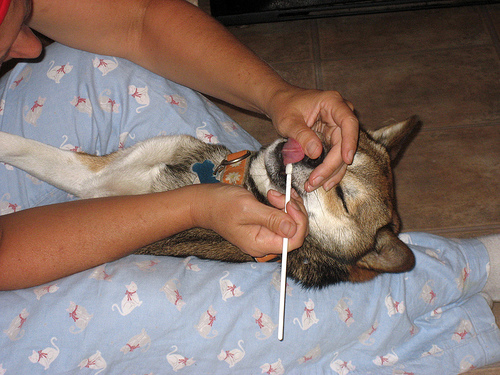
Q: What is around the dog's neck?
A: It's collar.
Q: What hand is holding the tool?
A: The right hand.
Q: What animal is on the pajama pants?
A: A cat.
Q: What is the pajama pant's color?
A: Blue.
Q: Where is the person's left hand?
A: Over the dogs face.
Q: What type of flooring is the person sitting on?
A: Tile.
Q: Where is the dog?
A: Lap.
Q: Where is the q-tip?
A: Right hand.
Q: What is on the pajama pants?
A: Cats.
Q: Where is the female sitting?
A: Floor.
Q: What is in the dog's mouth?
A: Q tip.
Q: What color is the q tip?
A: White.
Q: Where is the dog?
A: The womans lap.